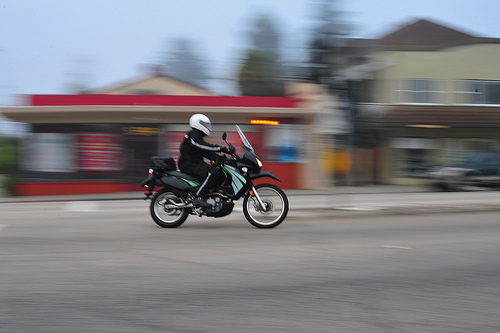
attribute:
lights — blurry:
[238, 115, 282, 130]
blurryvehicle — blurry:
[426, 160, 492, 192]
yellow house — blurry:
[359, 42, 499, 190]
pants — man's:
[182, 157, 234, 205]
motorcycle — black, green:
[142, 127, 289, 227]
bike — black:
[146, 159, 296, 232]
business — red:
[20, 68, 312, 189]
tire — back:
[144, 183, 193, 230]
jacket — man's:
[176, 130, 218, 190]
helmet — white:
[188, 112, 214, 137]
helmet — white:
[181, 114, 221, 135]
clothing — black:
[176, 127, 221, 200]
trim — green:
[220, 160, 249, 201]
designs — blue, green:
[223, 163, 245, 201]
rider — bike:
[177, 109, 230, 211]